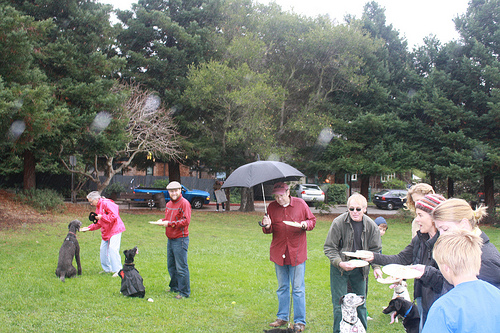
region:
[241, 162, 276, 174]
BLACK UMBRELLA UP IN THE AIR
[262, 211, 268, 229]
MAN HOLDING A UMBRELLA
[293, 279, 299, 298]
MAN WEARING BLUE JEANS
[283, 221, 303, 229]
MAN HOLDING A PLATE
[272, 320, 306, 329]
MAN WEARING BROWN SHOES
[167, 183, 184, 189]
MAN WEARING A HAT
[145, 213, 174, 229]
MAN HOLDING A PLATE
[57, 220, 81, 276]
DOG SITTING IN GRASS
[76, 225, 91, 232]
WOMAN FEEDING THE DOG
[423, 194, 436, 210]
HAT ON WOMAN HEAD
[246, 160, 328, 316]
A man standing under the umbrella.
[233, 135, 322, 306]
A man holding a black umbrella.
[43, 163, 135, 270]
The lady feeding the dog.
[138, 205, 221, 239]
The man is holding a plate.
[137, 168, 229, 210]
A blue truck parked on side of road.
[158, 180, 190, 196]
The man is wearing a hat.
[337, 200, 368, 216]
The person is wearing glasses.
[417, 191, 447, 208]
The cap has stripes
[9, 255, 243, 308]
The gress is green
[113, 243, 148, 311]
Black dog sitting on the grass.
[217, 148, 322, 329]
A man holding an umbrella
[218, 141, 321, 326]
A man holding a black umbrella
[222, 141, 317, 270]
A man wearing a red shirt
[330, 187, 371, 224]
A man wearing sunglasses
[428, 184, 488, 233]
A woman with blond hair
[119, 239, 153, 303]
A black dog standing on grass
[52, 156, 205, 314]
Two people with two dogs in a field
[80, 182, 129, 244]
A lady wearing a pink jacket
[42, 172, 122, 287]
A person feeding a dog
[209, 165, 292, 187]
THE Umbrella is black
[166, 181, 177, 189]
hat on the man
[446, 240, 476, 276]
back of the head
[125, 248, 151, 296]
the dog is black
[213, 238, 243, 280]
the grass is short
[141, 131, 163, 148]
no leaves on tree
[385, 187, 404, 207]
the car is parked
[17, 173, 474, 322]
people are standing in the park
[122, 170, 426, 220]
Parked vehicles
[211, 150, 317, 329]
A person standing under an umbrella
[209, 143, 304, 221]
A black umbrella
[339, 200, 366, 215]
A pair of sunglasses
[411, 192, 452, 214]
A striped tobogan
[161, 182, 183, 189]
A beige cap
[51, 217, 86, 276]
A grey dog sitting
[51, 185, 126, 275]
A person petting a dog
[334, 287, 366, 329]
A white dog with spots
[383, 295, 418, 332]
A black dog with a blue collar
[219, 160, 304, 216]
An umbrella in a hand.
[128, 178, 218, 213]
a blue truck in the back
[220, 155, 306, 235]
an open umbrella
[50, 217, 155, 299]
two black dogs sitting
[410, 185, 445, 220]
a striped stocking hat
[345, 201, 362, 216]
dark sunglasses worn by an old man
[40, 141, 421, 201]
houses in the background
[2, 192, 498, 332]
grass covered ground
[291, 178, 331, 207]
a parked white car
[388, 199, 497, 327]
woman with hair in a ponytail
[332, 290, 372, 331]
a white dog with black ears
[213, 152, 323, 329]
A man holding a black umbrella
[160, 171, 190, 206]
Hat on a man's head